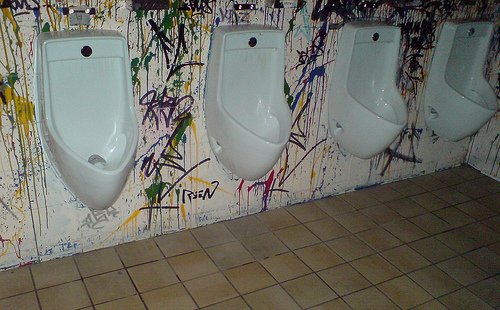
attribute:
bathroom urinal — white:
[29, 25, 146, 232]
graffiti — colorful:
[134, 25, 222, 222]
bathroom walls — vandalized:
[0, 3, 452, 164]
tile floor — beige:
[266, 224, 469, 305]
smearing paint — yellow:
[1, 80, 51, 249]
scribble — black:
[116, 47, 207, 208]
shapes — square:
[269, 208, 478, 300]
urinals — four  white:
[18, 28, 495, 210]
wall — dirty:
[18, 31, 478, 183]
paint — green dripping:
[132, 14, 204, 222]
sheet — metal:
[56, 1, 101, 30]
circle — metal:
[78, 42, 91, 55]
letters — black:
[170, 176, 225, 206]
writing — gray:
[67, 194, 120, 235]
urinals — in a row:
[25, 18, 497, 186]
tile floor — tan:
[4, 160, 497, 304]